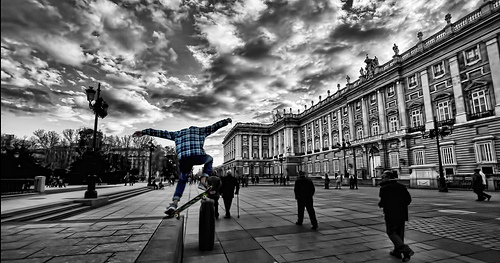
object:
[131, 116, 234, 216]
boy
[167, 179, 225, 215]
board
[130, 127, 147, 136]
hands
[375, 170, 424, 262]
people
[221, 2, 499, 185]
building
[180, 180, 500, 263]
street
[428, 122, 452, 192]
light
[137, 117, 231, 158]
shirt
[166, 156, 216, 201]
trousers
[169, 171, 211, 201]
up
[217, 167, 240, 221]
man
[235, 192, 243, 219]
cane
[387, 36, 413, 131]
pillars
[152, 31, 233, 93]
sun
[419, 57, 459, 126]
windows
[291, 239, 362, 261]
stones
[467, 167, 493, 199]
people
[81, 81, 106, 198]
pole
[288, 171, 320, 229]
man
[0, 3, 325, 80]
clouds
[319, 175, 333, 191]
person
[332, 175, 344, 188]
person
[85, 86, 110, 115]
lamp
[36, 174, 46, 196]
can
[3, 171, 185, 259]
sidewalk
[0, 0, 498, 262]
photo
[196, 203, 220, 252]
board